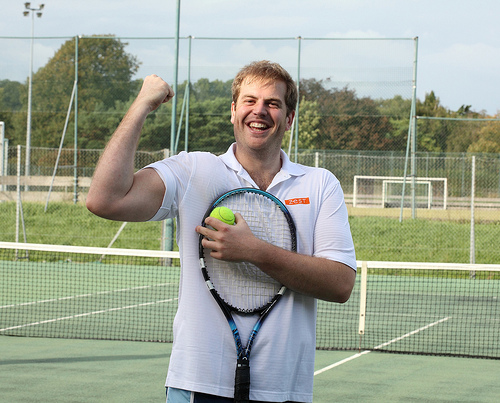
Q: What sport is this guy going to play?
A: Tennis.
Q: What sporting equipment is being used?
A: Racket and ball.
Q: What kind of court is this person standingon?
A: Tennis court.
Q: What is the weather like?
A: Sunny.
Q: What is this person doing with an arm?
A: Showing off a muscle.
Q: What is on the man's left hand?
A: A tennis ball.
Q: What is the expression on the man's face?
A: Smiling.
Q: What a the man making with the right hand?
A: A fist.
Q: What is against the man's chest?
A: A racket.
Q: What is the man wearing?
A: A white polo shirt.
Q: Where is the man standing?
A: Tennis court.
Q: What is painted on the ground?
A: White lines.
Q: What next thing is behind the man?
A: A net.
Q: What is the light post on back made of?
A: Metal.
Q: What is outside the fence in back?
A: Trees.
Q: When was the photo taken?
A: During the daytime.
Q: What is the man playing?
A: Tennis.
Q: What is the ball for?
A: Hitting.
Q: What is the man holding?
A: Racket.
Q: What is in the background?
A: Trees.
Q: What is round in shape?
A: The green ball.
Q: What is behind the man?
A: A net.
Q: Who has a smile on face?
A: The man.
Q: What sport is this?
A: Tennis.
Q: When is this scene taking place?
A: Daytime.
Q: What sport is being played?
A: Tennis.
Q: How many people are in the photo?
A: One.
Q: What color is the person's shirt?
A: White and orange.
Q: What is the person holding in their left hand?
A: Tennis ball.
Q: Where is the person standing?
A: Tennis court.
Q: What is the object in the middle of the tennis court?
A: Net.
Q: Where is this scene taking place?
A: At the tennis courts.